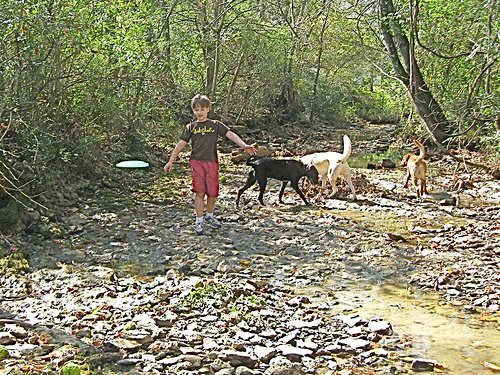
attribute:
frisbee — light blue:
[106, 152, 151, 174]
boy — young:
[164, 92, 259, 234]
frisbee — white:
[114, 155, 151, 170]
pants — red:
[187, 156, 219, 198]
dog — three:
[234, 153, 325, 210]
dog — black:
[232, 159, 321, 210]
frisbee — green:
[112, 159, 150, 171]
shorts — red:
[187, 163, 214, 198]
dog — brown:
[402, 148, 434, 194]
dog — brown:
[391, 135, 431, 202]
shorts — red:
[188, 164, 222, 191]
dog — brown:
[394, 135, 428, 193]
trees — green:
[0, 0, 499, 217]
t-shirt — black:
[180, 118, 230, 164]